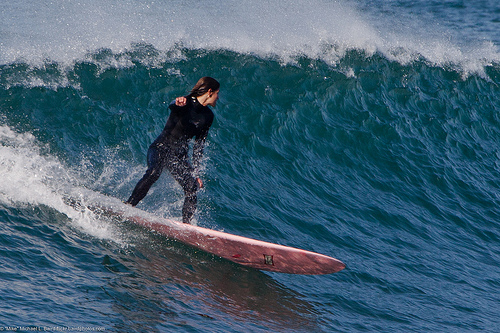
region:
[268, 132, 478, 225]
The water in the ocean is blue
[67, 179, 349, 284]
The surfboard is the color blue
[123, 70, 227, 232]
The surfer is wearing a wet suit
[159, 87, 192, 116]
The arm of the surfer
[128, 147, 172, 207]
The leg of the surfer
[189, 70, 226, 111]
The head of the surfer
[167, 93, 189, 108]
The hand of the surfer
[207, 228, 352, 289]
The front of the surfboard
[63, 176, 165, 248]
The back of the surfboard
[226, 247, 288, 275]
The logo on the surfboard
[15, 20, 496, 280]
picture taken outdoors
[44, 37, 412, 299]
Picture taken during the day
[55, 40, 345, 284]
a woman surfer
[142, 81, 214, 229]
the woman is wearing a body suit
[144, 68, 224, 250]
the body suit is black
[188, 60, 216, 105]
the woman has long hair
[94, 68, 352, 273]
the woman is standing on the board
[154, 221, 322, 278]
the board is light pink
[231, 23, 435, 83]
the wave is cresting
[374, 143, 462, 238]
the water is aqua in color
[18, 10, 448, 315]
This is in the ocean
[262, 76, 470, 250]
The water is turqoise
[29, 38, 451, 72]
The crest of the wave is white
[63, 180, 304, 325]
This is surfboard for riding waves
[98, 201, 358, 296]
The surfboard is pink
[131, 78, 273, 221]
This woman is surfing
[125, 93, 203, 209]
She is wearing a wetsuit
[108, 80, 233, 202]
The wetsuit is black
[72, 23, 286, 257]
The woman is wet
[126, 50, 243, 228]
This is a woman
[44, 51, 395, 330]
a woman skating on water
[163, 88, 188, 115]
Hand of a woman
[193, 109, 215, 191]
Hand of a woman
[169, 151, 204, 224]
Leg of a woman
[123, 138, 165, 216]
Leg of a woman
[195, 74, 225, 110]
Head of a woman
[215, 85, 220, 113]
Face of a woman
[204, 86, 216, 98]
Ear of a woman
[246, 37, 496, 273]
This is a mass of water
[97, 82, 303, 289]
One woman is surfing.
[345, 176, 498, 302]
water is blue color.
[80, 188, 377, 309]
Surfing board is white color.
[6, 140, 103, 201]
Water is splashing.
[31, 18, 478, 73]
waves are white color.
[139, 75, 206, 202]
Woman is in black suit.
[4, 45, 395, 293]
Day time picture.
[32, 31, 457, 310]
Picture is taken in beach.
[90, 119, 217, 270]
Woman is standing in surf board.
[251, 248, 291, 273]
Sticker is uner the board.